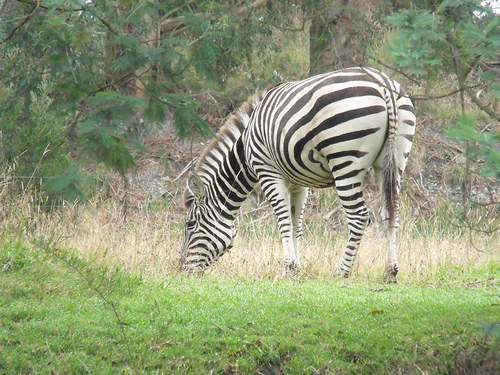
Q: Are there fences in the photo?
A: No, there are no fences.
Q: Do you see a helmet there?
A: No, there are no helmets.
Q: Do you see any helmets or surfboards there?
A: No, there are no helmets or surfboards.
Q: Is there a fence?
A: No, there are no fences.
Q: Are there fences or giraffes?
A: No, there are no fences or giraffes.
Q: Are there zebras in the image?
A: Yes, there is a zebra.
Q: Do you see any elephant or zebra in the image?
A: Yes, there is a zebra.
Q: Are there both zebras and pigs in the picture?
A: No, there is a zebra but no pigs.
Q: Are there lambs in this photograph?
A: No, there are no lambs.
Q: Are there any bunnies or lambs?
A: No, there are no lambs or bunnies.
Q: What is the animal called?
A: The animal is a zebra.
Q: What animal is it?
A: The animal is a zebra.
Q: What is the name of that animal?
A: This is a zebra.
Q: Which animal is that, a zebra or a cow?
A: This is a zebra.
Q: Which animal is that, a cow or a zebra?
A: This is a zebra.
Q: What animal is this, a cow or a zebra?
A: This is a zebra.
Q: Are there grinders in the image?
A: No, there are no grinders.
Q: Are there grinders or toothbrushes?
A: No, there are no grinders or toothbrushes.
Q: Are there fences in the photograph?
A: No, there are no fences.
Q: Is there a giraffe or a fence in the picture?
A: No, there are no fences or giraffes.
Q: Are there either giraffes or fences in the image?
A: No, there are no fences or giraffes.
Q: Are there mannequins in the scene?
A: No, there are no mannequins.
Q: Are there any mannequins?
A: No, there are no mannequins.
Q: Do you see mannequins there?
A: No, there are no mannequins.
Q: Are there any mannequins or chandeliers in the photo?
A: No, there are no mannequins or chandeliers.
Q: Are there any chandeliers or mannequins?
A: No, there are no mannequins or chandeliers.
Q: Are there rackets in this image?
A: No, there are no rackets.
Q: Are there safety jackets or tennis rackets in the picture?
A: No, there are no tennis rackets or safety jackets.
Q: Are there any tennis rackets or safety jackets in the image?
A: No, there are no tennis rackets or safety jackets.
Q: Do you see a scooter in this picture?
A: No, there are no scooters.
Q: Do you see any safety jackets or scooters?
A: No, there are no scooters or safety jackets.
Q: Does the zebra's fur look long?
A: Yes, the fur is long.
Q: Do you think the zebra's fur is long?
A: Yes, the fur is long.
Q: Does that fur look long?
A: Yes, the fur is long.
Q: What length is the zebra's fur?
A: The fur is long.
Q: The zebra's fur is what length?
A: The fur is long.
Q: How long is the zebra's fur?
A: The fur is long.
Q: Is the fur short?
A: No, the fur is long.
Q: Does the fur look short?
A: No, the fur is long.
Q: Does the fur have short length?
A: No, the fur is long.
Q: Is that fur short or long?
A: The fur is long.